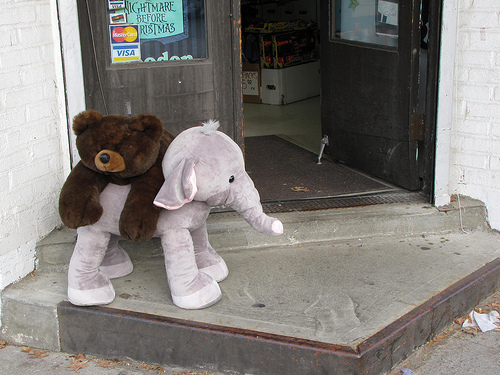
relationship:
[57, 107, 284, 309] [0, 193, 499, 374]
animals on steps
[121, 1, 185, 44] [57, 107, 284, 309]
advertisement above bears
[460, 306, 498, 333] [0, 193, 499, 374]
trash by steps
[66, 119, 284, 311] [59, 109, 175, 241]
elephant with bear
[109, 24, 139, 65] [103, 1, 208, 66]
logos on window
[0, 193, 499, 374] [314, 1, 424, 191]
step in front of door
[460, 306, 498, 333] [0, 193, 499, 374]
trash by stoop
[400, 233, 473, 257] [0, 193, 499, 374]
stains on stoop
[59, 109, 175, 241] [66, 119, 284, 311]
bear on elephant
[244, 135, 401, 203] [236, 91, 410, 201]
carpet on floor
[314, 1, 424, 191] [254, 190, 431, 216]
door has jamb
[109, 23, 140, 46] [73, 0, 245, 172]
sign on door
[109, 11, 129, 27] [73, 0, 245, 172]
sign on door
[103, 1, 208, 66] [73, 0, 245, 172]
window on door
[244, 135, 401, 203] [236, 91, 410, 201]
mat on floor